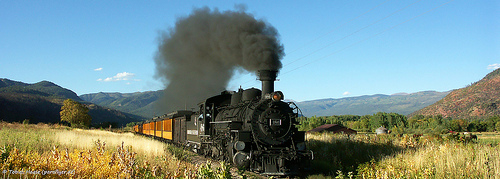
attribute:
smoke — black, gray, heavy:
[183, 23, 277, 59]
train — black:
[147, 81, 320, 171]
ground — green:
[359, 140, 417, 173]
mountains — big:
[27, 76, 111, 100]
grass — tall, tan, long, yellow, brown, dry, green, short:
[61, 143, 130, 168]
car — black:
[173, 116, 185, 143]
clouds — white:
[93, 56, 139, 83]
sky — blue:
[311, 29, 375, 65]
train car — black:
[186, 111, 202, 142]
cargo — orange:
[144, 119, 169, 137]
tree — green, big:
[55, 95, 94, 127]